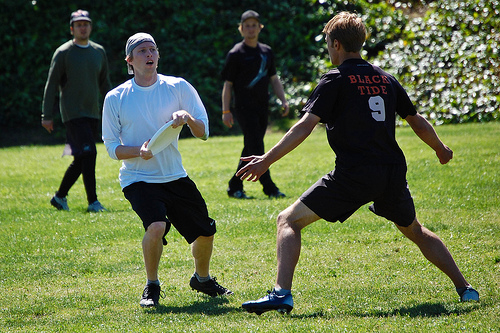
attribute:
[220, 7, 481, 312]
man — cute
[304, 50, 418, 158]
shirt — black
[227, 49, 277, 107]
tshirt — black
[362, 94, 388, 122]
9 — white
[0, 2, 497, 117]
plant — White 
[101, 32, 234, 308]
man — attractive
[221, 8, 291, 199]
person — walking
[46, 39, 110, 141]
shirt — long sleeve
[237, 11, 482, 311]
person — walking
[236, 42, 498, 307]
person — playing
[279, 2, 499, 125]
bush — white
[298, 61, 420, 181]
shirt — dark